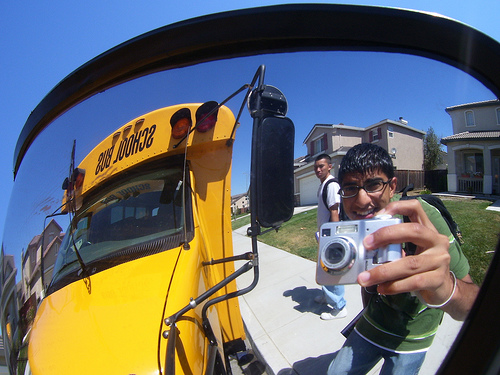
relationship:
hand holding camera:
[357, 198, 452, 297] [317, 223, 398, 275]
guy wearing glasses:
[325, 141, 478, 373] [335, 178, 393, 196]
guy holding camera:
[310, 154, 346, 321] [312, 215, 404, 287]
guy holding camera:
[325, 141, 478, 373] [315, 218, 403, 285]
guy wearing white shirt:
[310, 154, 346, 321] [310, 177, 341, 223]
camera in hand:
[319, 214, 415, 285] [357, 201, 452, 304]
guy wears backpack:
[325, 141, 481, 373] [416, 189, 469, 266]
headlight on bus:
[170, 115, 190, 137] [13, 61, 295, 373]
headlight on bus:
[45, 94, 231, 184] [38, 59, 291, 368]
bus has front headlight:
[1, 63, 296, 374] [67, 165, 87, 185]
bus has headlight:
[1, 63, 296, 374] [192, 101, 221, 131]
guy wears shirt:
[325, 141, 481, 373] [344, 197, 472, 361]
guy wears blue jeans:
[325, 141, 481, 373] [323, 328, 426, 374]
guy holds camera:
[325, 141, 481, 373] [312, 215, 404, 287]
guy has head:
[325, 141, 481, 373] [329, 153, 398, 218]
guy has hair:
[325, 141, 481, 373] [337, 142, 394, 178]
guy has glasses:
[325, 141, 481, 373] [334, 177, 392, 199]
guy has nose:
[325, 141, 481, 373] [354, 188, 371, 208]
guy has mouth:
[325, 141, 481, 373] [349, 205, 379, 217]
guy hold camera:
[325, 141, 481, 373] [315, 220, 405, 272]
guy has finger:
[325, 141, 481, 373] [388, 278, 427, 300]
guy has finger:
[325, 141, 481, 373] [386, 255, 416, 279]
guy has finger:
[325, 141, 481, 373] [383, 220, 420, 246]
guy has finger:
[325, 141, 481, 373] [386, 195, 424, 218]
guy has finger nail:
[325, 141, 481, 373] [356, 269, 371, 288]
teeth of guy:
[349, 208, 384, 222] [325, 141, 481, 373]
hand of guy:
[357, 201, 452, 304] [325, 141, 481, 373]